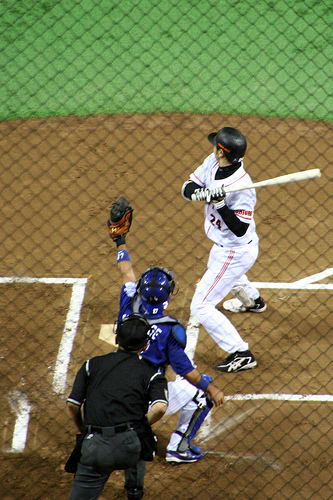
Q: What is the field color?
A: Green.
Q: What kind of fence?
A: Chainlink.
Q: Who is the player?
A: Batcatcher.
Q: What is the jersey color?
A: Blue.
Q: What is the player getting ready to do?
A: Swing the bat.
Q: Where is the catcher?
A: Behind the batter.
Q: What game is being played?
A: Baseball.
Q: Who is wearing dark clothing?
A: The umpire.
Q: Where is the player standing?
A: Home plate.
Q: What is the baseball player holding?
A: A bat.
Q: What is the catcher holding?
A: A mitt.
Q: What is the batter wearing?
A: A uniform.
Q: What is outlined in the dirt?
A: White lines.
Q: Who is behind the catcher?
A: Umpire.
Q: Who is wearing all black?
A: Umpire.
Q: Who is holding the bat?
A: A man.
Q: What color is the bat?
A: White.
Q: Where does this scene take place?
A: On a baseball field.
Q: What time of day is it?
A: Daytime.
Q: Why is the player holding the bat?
A: He is preparing to hit a baseball.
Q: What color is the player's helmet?
A: Black.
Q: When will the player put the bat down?
A: After he hits the baseball.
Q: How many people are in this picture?
A: Three.